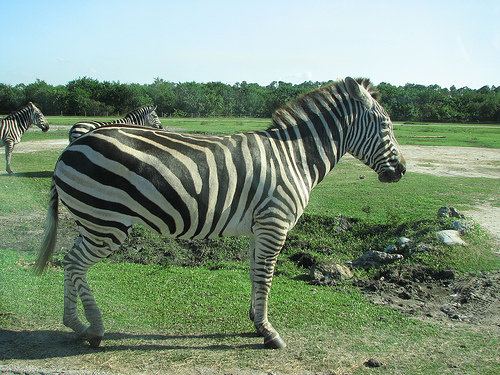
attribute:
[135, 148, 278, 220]
stripes — black, white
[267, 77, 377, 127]
mane — white, Black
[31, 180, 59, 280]
tail — White 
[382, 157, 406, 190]
nose — black 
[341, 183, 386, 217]
grass — Green 